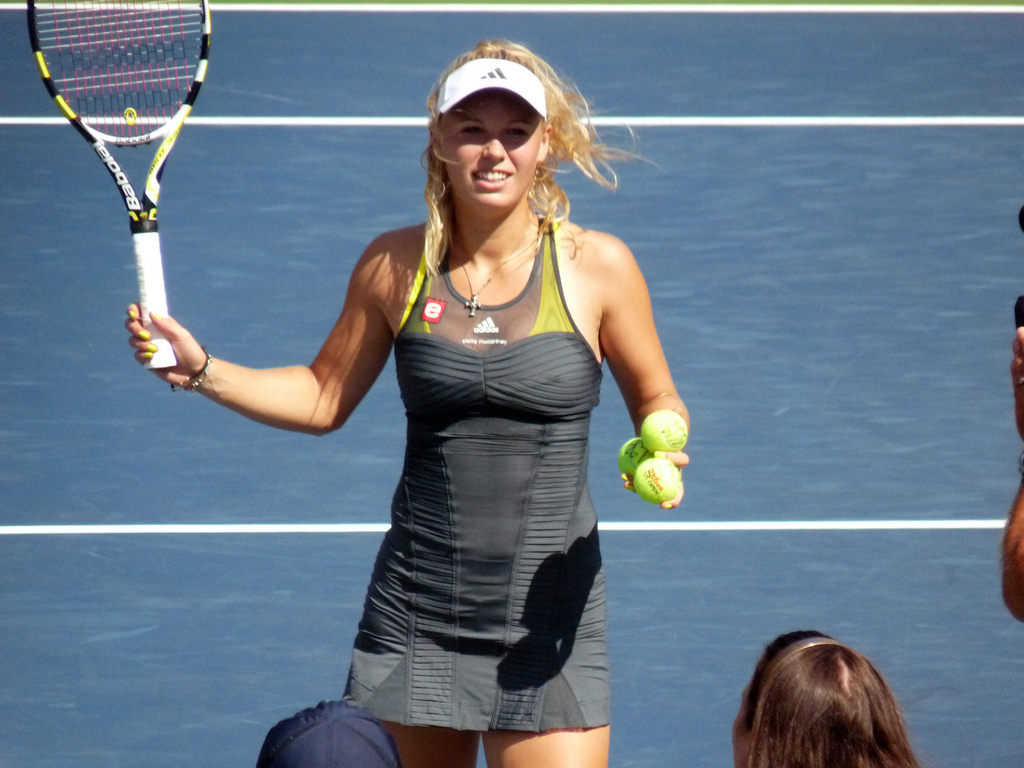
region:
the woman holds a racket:
[29, 0, 211, 373]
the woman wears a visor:
[438, 66, 547, 118]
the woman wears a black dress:
[338, 225, 617, 710]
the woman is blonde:
[411, 22, 637, 285]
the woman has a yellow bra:
[401, 206, 564, 346]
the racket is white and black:
[25, 4, 213, 377]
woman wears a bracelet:
[173, 350, 216, 395]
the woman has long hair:
[408, 42, 653, 287]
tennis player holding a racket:
[24, 0, 692, 763]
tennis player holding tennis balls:
[125, 40, 694, 764]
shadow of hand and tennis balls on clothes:
[495, 521, 604, 696]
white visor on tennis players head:
[432, 57, 550, 121]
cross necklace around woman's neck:
[442, 228, 550, 321]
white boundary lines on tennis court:
[3, 515, 1021, 536]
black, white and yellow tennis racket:
[24, 0, 215, 373]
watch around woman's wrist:
[183, 347, 213, 392]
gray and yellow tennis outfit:
[345, 214, 611, 730]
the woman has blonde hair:
[370, 20, 621, 296]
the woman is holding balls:
[579, 339, 735, 535]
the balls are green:
[580, 383, 720, 587]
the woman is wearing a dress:
[251, 2, 672, 731]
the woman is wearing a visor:
[381, 19, 574, 176]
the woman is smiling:
[386, 52, 549, 230]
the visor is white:
[266, 0, 633, 258]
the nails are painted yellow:
[93, 286, 193, 375]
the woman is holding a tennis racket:
[4, 0, 309, 456]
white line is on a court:
[0, 116, 1022, 130]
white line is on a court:
[4, 513, 1022, 534]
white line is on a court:
[0, 7, 1022, 20]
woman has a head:
[437, 66, 552, 213]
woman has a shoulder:
[356, 222, 423, 339]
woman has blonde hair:
[423, 39, 665, 292]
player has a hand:
[131, 305, 204, 398]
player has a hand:
[621, 445, 691, 515]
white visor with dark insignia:
[432, 55, 551, 129]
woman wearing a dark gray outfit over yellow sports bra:
[127, 39, 698, 764]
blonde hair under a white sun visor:
[417, 40, 642, 276]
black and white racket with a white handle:
[25, 2, 218, 376]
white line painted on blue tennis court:
[4, 104, 1022, 147]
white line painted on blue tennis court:
[3, 508, 1022, 540]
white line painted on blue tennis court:
[4, 2, 1019, 13]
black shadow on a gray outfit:
[495, 524, 610, 698]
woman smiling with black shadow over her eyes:
[442, 99, 538, 211]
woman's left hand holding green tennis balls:
[613, 404, 690, 513]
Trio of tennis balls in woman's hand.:
[611, 409, 697, 512]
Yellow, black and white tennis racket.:
[21, 1, 219, 371]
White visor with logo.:
[434, 56, 553, 121]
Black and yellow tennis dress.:
[337, 211, 617, 743]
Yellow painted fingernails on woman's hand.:
[119, 295, 159, 372]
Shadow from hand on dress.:
[491, 513, 615, 694]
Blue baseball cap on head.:
[253, 696, 408, 767]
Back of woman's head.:
[731, 621, 924, 765]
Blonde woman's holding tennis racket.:
[20, 2, 714, 740]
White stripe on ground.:
[605, 510, 1007, 543]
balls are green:
[610, 404, 724, 521]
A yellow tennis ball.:
[635, 465, 678, 501]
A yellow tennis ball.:
[612, 434, 652, 476]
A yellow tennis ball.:
[651, 419, 687, 457]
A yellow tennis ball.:
[628, 456, 666, 502]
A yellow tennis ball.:
[623, 434, 647, 460]